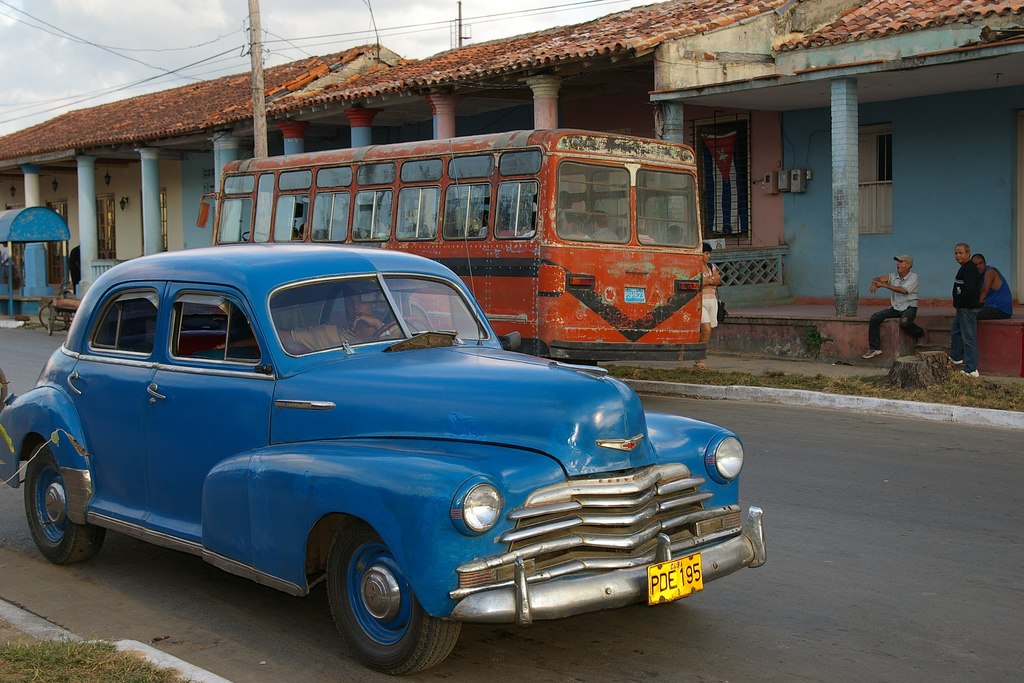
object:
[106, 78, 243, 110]
tiles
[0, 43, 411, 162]
roof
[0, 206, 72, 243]
covering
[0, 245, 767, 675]
car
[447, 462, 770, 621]
grill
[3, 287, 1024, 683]
street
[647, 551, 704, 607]
plate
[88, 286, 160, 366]
windows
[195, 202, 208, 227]
mirror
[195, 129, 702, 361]
bus